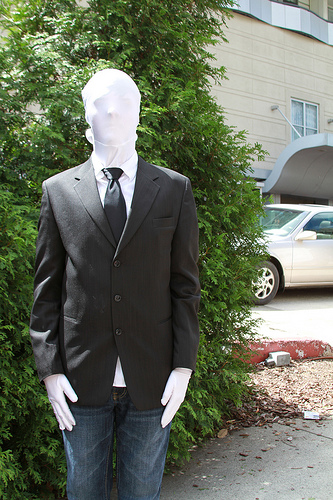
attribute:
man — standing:
[27, 69, 201, 494]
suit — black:
[27, 162, 198, 406]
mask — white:
[82, 68, 141, 158]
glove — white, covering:
[158, 363, 192, 427]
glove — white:
[43, 371, 79, 433]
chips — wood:
[233, 358, 332, 413]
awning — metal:
[264, 133, 329, 197]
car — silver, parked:
[223, 203, 331, 298]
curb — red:
[224, 338, 330, 366]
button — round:
[112, 256, 122, 269]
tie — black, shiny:
[103, 166, 127, 247]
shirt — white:
[91, 148, 138, 219]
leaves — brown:
[219, 386, 298, 432]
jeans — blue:
[62, 391, 168, 499]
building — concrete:
[184, 4, 329, 207]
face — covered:
[92, 96, 134, 145]